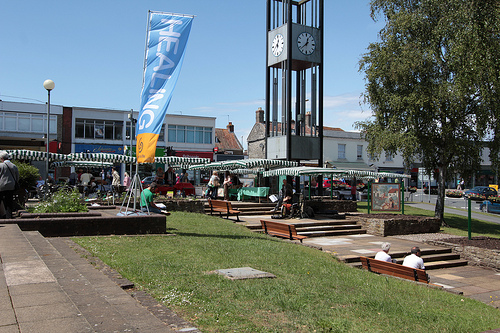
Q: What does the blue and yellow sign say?
A: Healing.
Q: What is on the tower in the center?
A: A clock face.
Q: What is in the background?
A: Buildings.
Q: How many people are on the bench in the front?
A: Two.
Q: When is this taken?
A: Daytime.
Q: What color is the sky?
A: Blue.